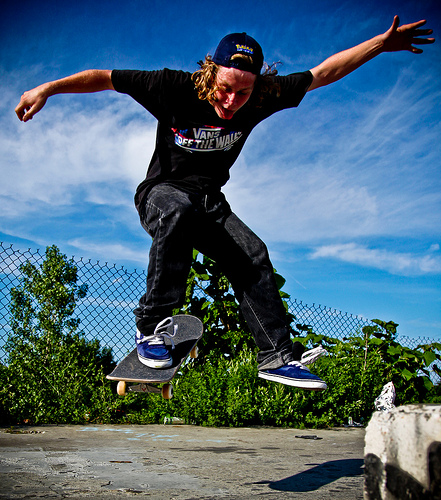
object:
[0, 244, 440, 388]
fence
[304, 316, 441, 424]
bushes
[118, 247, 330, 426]
bushes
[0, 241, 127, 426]
bushes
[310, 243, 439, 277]
grey cloud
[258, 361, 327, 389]
shoe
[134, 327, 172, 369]
shoe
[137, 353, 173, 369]
sole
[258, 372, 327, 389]
sole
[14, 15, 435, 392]
man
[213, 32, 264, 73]
baseball cap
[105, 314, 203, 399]
skateboard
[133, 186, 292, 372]
jeans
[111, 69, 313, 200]
shirt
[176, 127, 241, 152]
writing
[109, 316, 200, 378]
black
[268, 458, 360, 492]
shadow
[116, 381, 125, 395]
front wheels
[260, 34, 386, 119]
arm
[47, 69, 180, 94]
arm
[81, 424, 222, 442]
writing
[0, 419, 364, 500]
ground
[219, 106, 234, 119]
tongue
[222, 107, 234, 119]
mouth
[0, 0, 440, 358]
sky